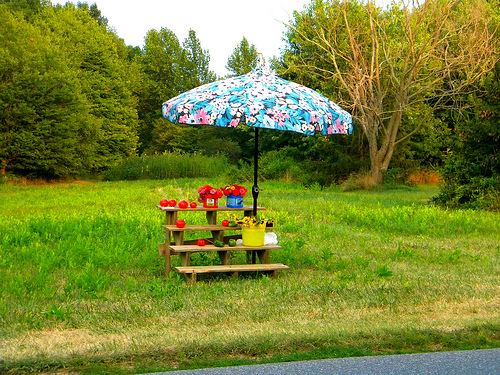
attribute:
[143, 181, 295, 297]
stand — small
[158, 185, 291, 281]
steps — wood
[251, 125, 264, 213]
pole — black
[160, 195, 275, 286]
stand — small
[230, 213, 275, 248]
bucket — yellow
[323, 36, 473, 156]
tree — bare 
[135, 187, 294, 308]
stand — small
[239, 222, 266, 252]
bucket — yellow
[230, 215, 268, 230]
sunflowers — yellow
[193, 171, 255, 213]
flowers — red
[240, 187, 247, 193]
flower — red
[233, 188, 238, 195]
flower — red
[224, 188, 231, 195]
flower — red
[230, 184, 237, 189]
flower — red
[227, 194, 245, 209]
bucket — blue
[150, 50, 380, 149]
umbrella — open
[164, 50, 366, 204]
umbrella — flower, patio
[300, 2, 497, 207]
tree — bare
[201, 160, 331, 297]
peppers — green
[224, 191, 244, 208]
container — blue